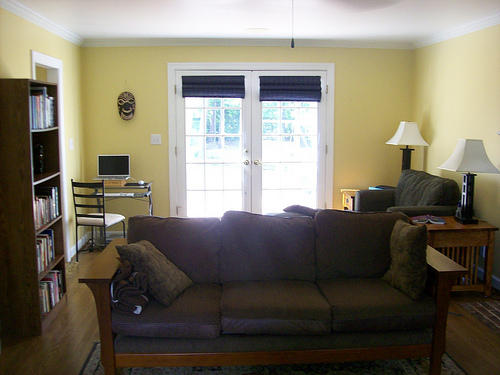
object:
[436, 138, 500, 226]
lamp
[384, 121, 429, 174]
lamp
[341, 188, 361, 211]
table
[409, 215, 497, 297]
table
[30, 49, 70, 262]
frame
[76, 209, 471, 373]
couch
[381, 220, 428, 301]
pillow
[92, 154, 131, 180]
computer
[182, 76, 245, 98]
shade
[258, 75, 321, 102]
shade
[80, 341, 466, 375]
rug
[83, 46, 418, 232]
wall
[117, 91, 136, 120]
mask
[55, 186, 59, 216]
books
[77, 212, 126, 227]
cushion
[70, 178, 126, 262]
chair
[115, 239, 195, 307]
pillow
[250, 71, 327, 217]
doors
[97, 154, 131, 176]
monitor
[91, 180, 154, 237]
desk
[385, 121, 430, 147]
shade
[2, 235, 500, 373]
floor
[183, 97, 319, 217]
outside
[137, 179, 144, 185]
mouse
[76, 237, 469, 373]
frame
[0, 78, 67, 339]
bookshelf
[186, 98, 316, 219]
light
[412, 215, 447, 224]
book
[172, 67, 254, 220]
door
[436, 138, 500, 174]
shade